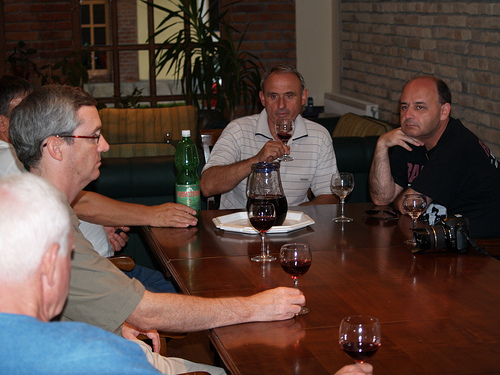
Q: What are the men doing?
A: Sitting.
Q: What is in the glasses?
A: Wine.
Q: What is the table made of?
A: Wood.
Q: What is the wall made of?
A: Stone.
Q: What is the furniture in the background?
A: Couch.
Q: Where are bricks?
A: On the walls.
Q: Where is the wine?
A: In glasses.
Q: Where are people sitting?
A: Around a table.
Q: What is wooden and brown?
A: Table.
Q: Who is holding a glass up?
A: Man at head of the table.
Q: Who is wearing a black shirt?
A: Man on the right.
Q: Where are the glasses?
A: On table.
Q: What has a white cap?
A: Green bottle.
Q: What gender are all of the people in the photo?
A: Male.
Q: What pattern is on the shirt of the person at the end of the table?
A: Striped.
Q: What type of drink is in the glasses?
A: Wine.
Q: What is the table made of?
A: Wood.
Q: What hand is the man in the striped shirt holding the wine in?
A: Right.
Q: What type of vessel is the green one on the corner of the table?
A: Soda bottle.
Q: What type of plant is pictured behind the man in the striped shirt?
A: Palm.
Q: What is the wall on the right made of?
A: Brick.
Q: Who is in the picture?
A: Five men.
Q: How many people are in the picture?
A: Five.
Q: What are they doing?
A: Drinking alcohol.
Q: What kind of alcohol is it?
A: Red wine.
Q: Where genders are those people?
A: Male.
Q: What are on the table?
A: Glasses and plates.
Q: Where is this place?
A: Restaurant.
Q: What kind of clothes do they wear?
A: Casual clothes.